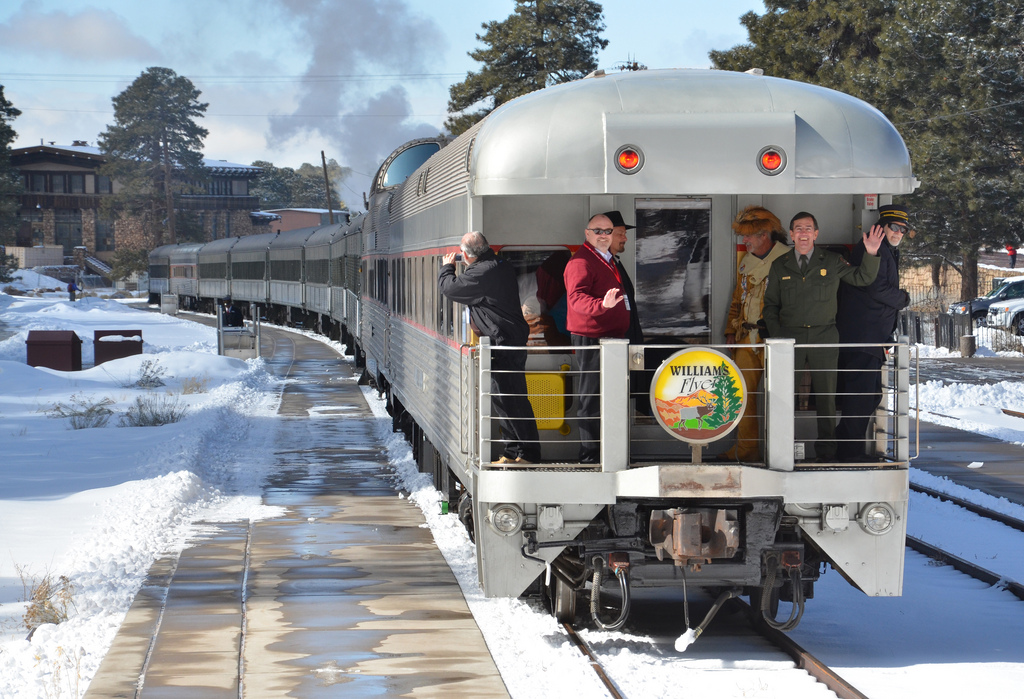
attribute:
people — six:
[431, 208, 922, 448]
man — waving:
[754, 206, 889, 455]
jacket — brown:
[752, 251, 886, 351]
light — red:
[605, 141, 649, 178]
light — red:
[754, 137, 794, 179]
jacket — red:
[560, 247, 628, 334]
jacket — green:
[759, 255, 880, 357]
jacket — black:
[848, 253, 913, 334]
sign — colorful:
[644, 342, 748, 448]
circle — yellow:
[644, 342, 751, 448]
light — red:
[612, 139, 647, 174]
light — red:
[750, 139, 792, 179]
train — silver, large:
[224, 57, 1005, 676]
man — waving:
[722, 197, 917, 442]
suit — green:
[783, 240, 881, 351]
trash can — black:
[8, 281, 183, 459]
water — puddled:
[183, 463, 385, 664]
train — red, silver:
[228, 102, 1002, 660]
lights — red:
[561, 80, 804, 214]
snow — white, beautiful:
[364, 374, 907, 686]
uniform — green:
[743, 190, 834, 432]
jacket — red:
[542, 251, 689, 373]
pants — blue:
[533, 312, 655, 434]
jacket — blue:
[432, 240, 541, 347]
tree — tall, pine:
[86, 46, 227, 211]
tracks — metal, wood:
[526, 569, 950, 691]